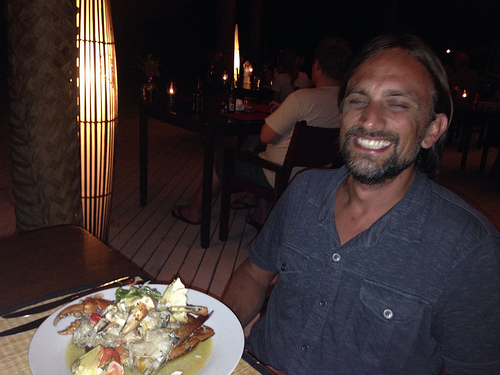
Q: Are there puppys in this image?
A: No, there are no puppys.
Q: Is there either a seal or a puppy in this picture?
A: No, there are no puppys or seals.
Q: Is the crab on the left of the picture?
A: Yes, the crab is on the left of the image.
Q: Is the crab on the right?
A: No, the crab is on the left of the image.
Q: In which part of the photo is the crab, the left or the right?
A: The crab is on the left of the image.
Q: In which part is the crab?
A: The crab is on the left of the image.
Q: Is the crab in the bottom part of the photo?
A: Yes, the crab is in the bottom of the image.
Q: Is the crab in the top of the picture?
A: No, the crab is in the bottom of the image.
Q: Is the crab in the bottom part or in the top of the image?
A: The crab is in the bottom of the image.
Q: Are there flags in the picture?
A: No, there are no flags.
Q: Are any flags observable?
A: No, there are no flags.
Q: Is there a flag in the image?
A: No, there are no flags.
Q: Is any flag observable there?
A: No, there are no flags.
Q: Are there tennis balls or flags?
A: No, there are no flags or tennis balls.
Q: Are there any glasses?
A: No, there are no glasses.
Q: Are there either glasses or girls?
A: No, there are no glasses or girls.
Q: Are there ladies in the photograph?
A: No, there are no ladies.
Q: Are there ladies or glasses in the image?
A: No, there are no ladies or glasses.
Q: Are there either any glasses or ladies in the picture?
A: No, there are no ladies or glasses.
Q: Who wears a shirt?
A: The man wears a shirt.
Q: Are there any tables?
A: Yes, there is a table.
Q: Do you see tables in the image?
A: Yes, there is a table.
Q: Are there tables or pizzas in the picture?
A: Yes, there is a table.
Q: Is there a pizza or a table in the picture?
A: Yes, there is a table.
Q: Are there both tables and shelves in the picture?
A: No, there is a table but no shelves.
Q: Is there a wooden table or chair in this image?
A: Yes, there is a wood table.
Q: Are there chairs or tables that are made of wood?
A: Yes, the table is made of wood.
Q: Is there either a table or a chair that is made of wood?
A: Yes, the table is made of wood.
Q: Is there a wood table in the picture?
A: Yes, there is a wood table.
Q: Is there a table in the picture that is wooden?
A: Yes, there is a table that is wooden.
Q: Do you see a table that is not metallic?
A: Yes, there is a wooden table.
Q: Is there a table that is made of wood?
A: Yes, there is a table that is made of wood.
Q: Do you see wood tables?
A: Yes, there is a table that is made of wood.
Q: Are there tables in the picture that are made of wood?
A: Yes, there is a table that is made of wood.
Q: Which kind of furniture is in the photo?
A: The furniture is a table.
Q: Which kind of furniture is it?
A: The piece of furniture is a table.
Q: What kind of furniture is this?
A: That is a table.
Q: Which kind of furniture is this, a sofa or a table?
A: That is a table.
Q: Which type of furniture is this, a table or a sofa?
A: That is a table.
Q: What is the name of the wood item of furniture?
A: The piece of furniture is a table.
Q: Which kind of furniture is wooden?
A: The furniture is a table.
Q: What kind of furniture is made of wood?
A: The furniture is a table.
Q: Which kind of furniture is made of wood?
A: The furniture is a table.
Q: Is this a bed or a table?
A: This is a table.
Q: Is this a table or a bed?
A: This is a table.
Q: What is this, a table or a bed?
A: This is a table.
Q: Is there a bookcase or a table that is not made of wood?
A: No, there is a table but it is made of wood.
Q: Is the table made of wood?
A: Yes, the table is made of wood.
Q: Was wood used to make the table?
A: Yes, the table is made of wood.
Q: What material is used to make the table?
A: The table is made of wood.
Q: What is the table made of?
A: The table is made of wood.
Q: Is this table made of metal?
A: No, the table is made of wood.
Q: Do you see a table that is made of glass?
A: No, there is a table but it is made of wood.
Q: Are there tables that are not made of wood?
A: No, there is a table but it is made of wood.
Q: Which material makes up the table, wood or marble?
A: The table is made of wood.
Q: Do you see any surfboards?
A: No, there are no surfboards.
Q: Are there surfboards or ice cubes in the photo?
A: No, there are no surfboards or ice cubes.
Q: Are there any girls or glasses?
A: No, there are no glasses or girls.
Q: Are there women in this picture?
A: No, there are no women.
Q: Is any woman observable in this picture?
A: No, there are no women.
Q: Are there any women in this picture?
A: No, there are no women.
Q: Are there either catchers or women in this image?
A: No, there are no women or catchers.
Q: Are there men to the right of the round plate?
A: Yes, there is a man to the right of the plate.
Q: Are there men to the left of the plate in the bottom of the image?
A: No, the man is to the right of the plate.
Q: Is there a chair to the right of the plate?
A: No, there is a man to the right of the plate.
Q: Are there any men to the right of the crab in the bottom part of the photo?
A: Yes, there is a man to the right of the crab.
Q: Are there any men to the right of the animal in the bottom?
A: Yes, there is a man to the right of the crab.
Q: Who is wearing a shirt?
A: The man is wearing a shirt.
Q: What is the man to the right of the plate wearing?
A: The man is wearing a shirt.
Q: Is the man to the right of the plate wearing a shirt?
A: Yes, the man is wearing a shirt.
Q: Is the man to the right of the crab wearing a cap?
A: No, the man is wearing a shirt.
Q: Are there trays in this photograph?
A: No, there are no trays.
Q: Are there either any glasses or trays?
A: No, there are no trays or glasses.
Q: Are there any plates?
A: Yes, there is a plate.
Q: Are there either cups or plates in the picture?
A: Yes, there is a plate.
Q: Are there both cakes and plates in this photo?
A: No, there is a plate but no cakes.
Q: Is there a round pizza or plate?
A: Yes, there is a round plate.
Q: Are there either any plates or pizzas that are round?
A: Yes, the plate is round.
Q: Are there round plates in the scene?
A: Yes, there is a round plate.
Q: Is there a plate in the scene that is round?
A: Yes, there is a plate that is round.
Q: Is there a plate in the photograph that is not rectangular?
A: Yes, there is a round plate.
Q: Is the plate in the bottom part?
A: Yes, the plate is in the bottom of the image.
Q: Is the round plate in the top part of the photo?
A: No, the plate is in the bottom of the image.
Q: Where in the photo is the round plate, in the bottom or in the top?
A: The plate is in the bottom of the image.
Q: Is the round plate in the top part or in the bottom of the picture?
A: The plate is in the bottom of the image.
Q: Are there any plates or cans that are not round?
A: No, there is a plate but it is round.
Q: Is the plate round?
A: Yes, the plate is round.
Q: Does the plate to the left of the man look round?
A: Yes, the plate is round.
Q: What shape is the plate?
A: The plate is round.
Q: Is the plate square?
A: No, the plate is round.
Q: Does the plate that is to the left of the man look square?
A: No, the plate is round.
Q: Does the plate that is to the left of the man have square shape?
A: No, the plate is round.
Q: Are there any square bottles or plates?
A: No, there is a plate but it is round.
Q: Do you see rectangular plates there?
A: No, there is a plate but it is round.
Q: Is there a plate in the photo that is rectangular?
A: No, there is a plate but it is round.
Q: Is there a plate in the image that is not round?
A: No, there is a plate but it is round.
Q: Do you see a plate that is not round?
A: No, there is a plate but it is round.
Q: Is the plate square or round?
A: The plate is round.